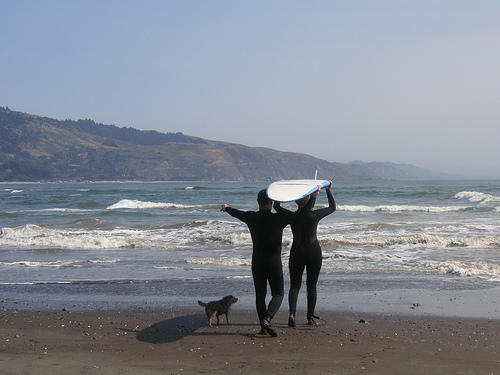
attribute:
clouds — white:
[250, 14, 447, 159]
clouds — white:
[457, 56, 497, 172]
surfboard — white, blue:
[265, 170, 331, 204]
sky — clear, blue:
[15, 9, 485, 124]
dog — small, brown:
[193, 292, 241, 327]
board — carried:
[264, 171, 332, 206]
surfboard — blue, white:
[264, 166, 334, 204]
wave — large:
[414, 175, 496, 230]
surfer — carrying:
[222, 180, 292, 340]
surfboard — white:
[262, 177, 329, 204]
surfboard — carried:
[261, 164, 349, 215]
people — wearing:
[206, 171, 357, 347]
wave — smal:
[412, 252, 498, 287]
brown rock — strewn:
[346, 305, 392, 335]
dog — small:
[198, 295, 237, 328]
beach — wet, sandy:
[1, 276, 498, 372]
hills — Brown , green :
[0, 107, 498, 181]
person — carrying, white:
[274, 184, 337, 326]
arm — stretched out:
[221, 195, 252, 224]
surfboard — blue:
[240, 163, 392, 219]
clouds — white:
[180, 59, 390, 142]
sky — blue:
[56, 3, 445, 168]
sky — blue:
[40, 14, 415, 162]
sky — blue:
[161, 21, 450, 151]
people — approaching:
[184, 195, 376, 328]